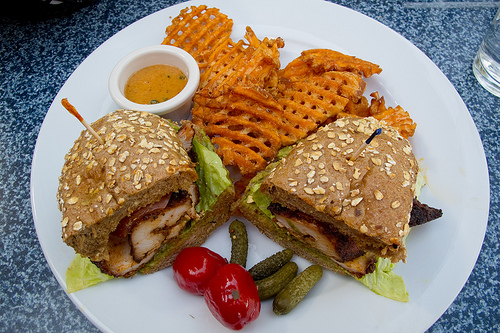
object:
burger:
[230, 116, 443, 302]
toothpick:
[61, 98, 104, 145]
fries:
[161, 5, 417, 176]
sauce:
[108, 45, 200, 126]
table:
[0, 15, 62, 88]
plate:
[30, 0, 490, 333]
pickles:
[229, 219, 323, 316]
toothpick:
[349, 128, 382, 162]